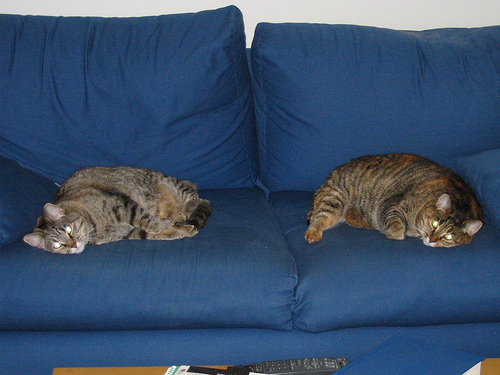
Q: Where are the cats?
A: On the couch.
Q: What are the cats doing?
A: Laying down.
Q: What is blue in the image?
A: The couch.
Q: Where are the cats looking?
A: At the camera.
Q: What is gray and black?
A: Cats.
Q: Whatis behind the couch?
A: Walls.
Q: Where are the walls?
A: Behind the couch.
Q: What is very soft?
A: The couch.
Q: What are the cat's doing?
A: Laying.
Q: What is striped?
A: The cat.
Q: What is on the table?
A: Remote.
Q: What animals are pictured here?
A: Cats.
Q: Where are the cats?
A: On the couch.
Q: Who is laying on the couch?
A: Cats.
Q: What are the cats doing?
A: Laying on the couch.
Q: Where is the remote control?
A: On the table in front of couch.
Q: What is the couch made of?
A: Blue fabric.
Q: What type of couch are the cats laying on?
A: Blue cushion couch.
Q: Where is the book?
A: On table in front of couch.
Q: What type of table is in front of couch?
A: Brown wooden.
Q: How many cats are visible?
A: Two.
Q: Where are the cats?
A: On the couch.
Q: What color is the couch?
A: Blue.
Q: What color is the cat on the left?
A: Gray and black.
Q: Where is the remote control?
A: On the table.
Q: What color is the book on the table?
A: Blue.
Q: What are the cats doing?
A: Laying down.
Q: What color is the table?
A: Tan.